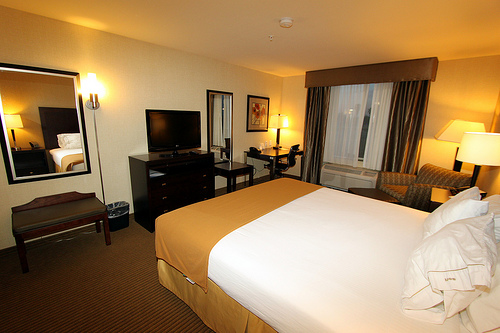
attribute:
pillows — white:
[397, 181, 499, 318]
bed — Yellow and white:
[144, 172, 497, 330]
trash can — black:
[104, 202, 133, 227]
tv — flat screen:
[140, 108, 201, 156]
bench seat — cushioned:
[8, 184, 112, 266]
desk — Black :
[235, 115, 361, 230]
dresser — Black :
[129, 154, 229, 206]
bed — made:
[125, 125, 444, 312]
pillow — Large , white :
[398, 210, 482, 311]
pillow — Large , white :
[418, 185, 485, 233]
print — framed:
[249, 98, 267, 132]